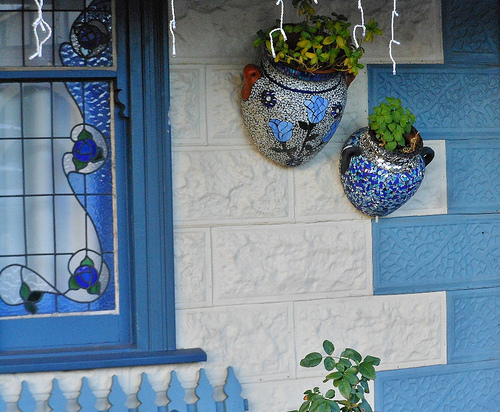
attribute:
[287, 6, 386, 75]
plants — green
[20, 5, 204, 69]
lights — white, hanging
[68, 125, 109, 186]
flowers — blue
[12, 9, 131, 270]
window — glass, blue, edge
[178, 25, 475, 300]
wall — blue, white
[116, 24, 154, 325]
sill — blue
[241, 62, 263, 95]
handle — small, brown, red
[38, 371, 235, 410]
fence — blue, decorative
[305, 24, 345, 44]
leaves — small, green, yellow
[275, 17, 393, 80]
plant — green, small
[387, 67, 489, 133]
tile — blue, textured, white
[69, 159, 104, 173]
leaf — green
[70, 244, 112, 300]
rose — blue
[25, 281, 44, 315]
leaves — green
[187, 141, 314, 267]
bricks — white, blue, rough, facade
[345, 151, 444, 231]
pot — blue, grey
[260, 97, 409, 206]
vases — small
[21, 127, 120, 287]
glass — stained